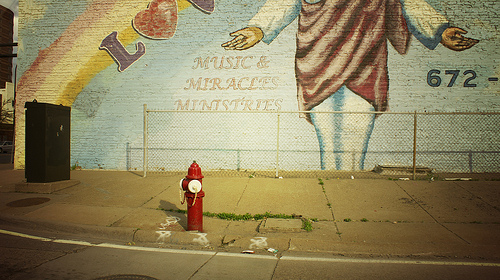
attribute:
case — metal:
[24, 98, 70, 181]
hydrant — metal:
[171, 157, 229, 239]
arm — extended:
[386, 0, 450, 59]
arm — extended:
[245, 1, 299, 46]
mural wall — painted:
[9, 4, 499, 173]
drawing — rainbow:
[2, 9, 199, 184]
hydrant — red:
[175, 159, 206, 240]